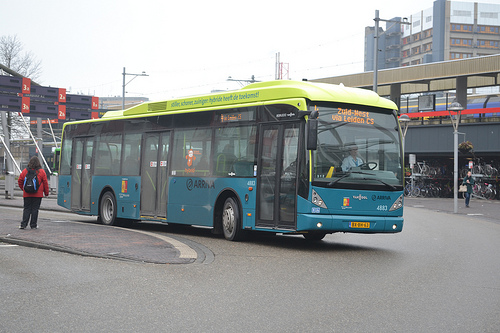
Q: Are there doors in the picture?
A: Yes, there is a door.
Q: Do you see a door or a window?
A: Yes, there is a door.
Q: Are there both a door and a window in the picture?
A: Yes, there are both a door and a window.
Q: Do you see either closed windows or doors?
A: Yes, there is a closed door.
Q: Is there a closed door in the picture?
A: Yes, there is a closed door.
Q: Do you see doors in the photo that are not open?
A: Yes, there is an closed door.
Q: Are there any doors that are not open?
A: Yes, there is an closed door.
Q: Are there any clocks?
A: No, there are no clocks.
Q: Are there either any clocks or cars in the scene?
A: No, there are no clocks or cars.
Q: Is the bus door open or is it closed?
A: The door is closed.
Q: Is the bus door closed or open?
A: The door is closed.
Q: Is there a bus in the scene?
A: Yes, there is a bus.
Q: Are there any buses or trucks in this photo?
A: Yes, there is a bus.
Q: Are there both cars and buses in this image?
A: No, there is a bus but no cars.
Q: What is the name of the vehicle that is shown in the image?
A: The vehicle is a bus.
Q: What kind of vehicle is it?
A: The vehicle is a bus.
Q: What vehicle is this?
A: That is a bus.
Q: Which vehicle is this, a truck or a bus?
A: That is a bus.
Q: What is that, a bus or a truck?
A: That is a bus.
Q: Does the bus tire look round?
A: Yes, the tire is round.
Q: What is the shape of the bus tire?
A: The tire is round.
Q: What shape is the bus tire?
A: The tire is round.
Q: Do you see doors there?
A: Yes, there is a door.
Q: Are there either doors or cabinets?
A: Yes, there is a door.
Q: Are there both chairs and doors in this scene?
A: No, there is a door but no chairs.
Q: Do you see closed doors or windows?
A: Yes, there is a closed door.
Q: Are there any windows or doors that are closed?
A: Yes, the door is closed.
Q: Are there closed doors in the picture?
A: Yes, there is a closed door.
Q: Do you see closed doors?
A: Yes, there is a closed door.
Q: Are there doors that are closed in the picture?
A: Yes, there is a closed door.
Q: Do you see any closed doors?
A: Yes, there is a closed door.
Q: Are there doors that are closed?
A: Yes, there is a door that is closed.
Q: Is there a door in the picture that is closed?
A: Yes, there is a door that is closed.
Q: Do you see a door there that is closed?
A: Yes, there is a door that is closed.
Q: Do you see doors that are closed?
A: Yes, there is a door that is closed.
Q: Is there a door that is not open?
A: Yes, there is an closed door.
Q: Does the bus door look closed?
A: Yes, the door is closed.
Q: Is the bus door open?
A: No, the door is closed.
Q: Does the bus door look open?
A: No, the door is closed.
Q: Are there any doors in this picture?
A: Yes, there is a door.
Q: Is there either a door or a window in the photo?
A: Yes, there is a door.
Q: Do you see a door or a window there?
A: Yes, there is a door.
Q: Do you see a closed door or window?
A: Yes, there is a closed door.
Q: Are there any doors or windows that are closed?
A: Yes, the door is closed.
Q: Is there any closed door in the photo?
A: Yes, there is a closed door.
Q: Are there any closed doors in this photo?
A: Yes, there is a closed door.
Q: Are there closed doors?
A: Yes, there is a closed door.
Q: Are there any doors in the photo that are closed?
A: Yes, there is a door that is closed.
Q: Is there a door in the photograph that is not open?
A: Yes, there is an closed door.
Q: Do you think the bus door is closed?
A: Yes, the door is closed.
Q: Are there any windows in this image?
A: Yes, there is a window.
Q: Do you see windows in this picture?
A: Yes, there is a window.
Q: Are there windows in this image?
A: Yes, there is a window.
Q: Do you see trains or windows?
A: Yes, there is a window.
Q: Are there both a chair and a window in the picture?
A: No, there is a window but no chairs.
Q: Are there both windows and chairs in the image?
A: No, there is a window but no chairs.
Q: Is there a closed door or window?
A: Yes, there is a closed window.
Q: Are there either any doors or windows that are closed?
A: Yes, the window is closed.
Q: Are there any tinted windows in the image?
A: Yes, there is a tinted window.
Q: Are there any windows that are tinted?
A: Yes, there is a window that is tinted.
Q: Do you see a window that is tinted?
A: Yes, there is a window that is tinted.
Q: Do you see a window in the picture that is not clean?
A: Yes, there is a tinted window.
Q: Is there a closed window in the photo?
A: Yes, there is a closed window.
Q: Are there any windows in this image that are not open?
A: Yes, there is an closed window.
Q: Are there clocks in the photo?
A: No, there are no clocks.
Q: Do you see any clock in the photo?
A: No, there are no clocks.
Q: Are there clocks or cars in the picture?
A: No, there are no clocks or cars.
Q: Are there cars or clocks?
A: No, there are no clocks or cars.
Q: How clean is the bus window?
A: The window is tinted.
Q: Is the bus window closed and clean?
A: No, the window is closed but tinted.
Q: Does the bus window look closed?
A: Yes, the window is closed.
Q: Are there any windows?
A: Yes, there is a window.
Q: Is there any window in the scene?
A: Yes, there is a window.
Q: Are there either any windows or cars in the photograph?
A: Yes, there is a window.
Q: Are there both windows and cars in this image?
A: No, there is a window but no cars.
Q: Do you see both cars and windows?
A: No, there is a window but no cars.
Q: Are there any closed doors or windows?
A: Yes, there is a closed window.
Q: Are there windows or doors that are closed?
A: Yes, the window is closed.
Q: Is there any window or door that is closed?
A: Yes, the window is closed.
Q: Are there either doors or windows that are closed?
A: Yes, the window is closed.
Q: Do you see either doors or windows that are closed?
A: Yes, the window is closed.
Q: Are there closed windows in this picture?
A: Yes, there is a closed window.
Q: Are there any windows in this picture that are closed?
A: Yes, there is a window that is closed.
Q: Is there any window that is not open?
A: Yes, there is an closed window.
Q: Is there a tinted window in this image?
A: Yes, there is a tinted window.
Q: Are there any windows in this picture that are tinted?
A: Yes, there is a window that is tinted.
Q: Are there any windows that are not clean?
A: Yes, there is a tinted window.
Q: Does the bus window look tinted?
A: Yes, the window is tinted.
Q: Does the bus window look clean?
A: No, the window is tinted.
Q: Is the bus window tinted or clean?
A: The window is tinted.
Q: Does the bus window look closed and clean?
A: No, the window is closed but tinted.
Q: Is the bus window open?
A: No, the window is closed.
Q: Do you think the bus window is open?
A: No, the window is closed.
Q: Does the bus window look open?
A: No, the window is closed.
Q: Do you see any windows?
A: Yes, there is a window.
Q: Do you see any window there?
A: Yes, there is a window.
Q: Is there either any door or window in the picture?
A: Yes, there is a window.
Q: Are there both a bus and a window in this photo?
A: Yes, there are both a window and a bus.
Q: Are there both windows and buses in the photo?
A: Yes, there are both a window and a bus.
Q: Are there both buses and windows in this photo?
A: Yes, there are both a window and a bus.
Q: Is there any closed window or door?
A: Yes, there is a closed window.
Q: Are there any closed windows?
A: Yes, there is a closed window.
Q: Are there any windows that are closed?
A: Yes, there is a window that is closed.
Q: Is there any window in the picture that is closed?
A: Yes, there is a window that is closed.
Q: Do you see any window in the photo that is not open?
A: Yes, there is an closed window.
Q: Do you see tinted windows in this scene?
A: Yes, there is a tinted window.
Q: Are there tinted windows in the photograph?
A: Yes, there is a tinted window.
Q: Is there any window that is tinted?
A: Yes, there is a window that is tinted.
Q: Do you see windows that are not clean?
A: Yes, there is a tinted window.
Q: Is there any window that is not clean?
A: Yes, there is a tinted window.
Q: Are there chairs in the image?
A: No, there are no chairs.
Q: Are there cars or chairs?
A: No, there are no chairs or cars.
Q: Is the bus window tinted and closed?
A: Yes, the window is tinted and closed.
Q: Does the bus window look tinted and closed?
A: Yes, the window is tinted and closed.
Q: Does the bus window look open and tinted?
A: No, the window is tinted but closed.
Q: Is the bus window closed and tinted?
A: Yes, the window is closed and tinted.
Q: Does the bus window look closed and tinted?
A: Yes, the window is closed and tinted.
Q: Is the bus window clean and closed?
A: No, the window is closed but tinted.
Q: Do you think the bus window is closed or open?
A: The window is closed.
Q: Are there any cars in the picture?
A: No, there are no cars.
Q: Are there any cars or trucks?
A: No, there are no cars or trucks.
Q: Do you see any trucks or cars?
A: No, there are no cars or trucks.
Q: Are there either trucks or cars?
A: No, there are no cars or trucks.